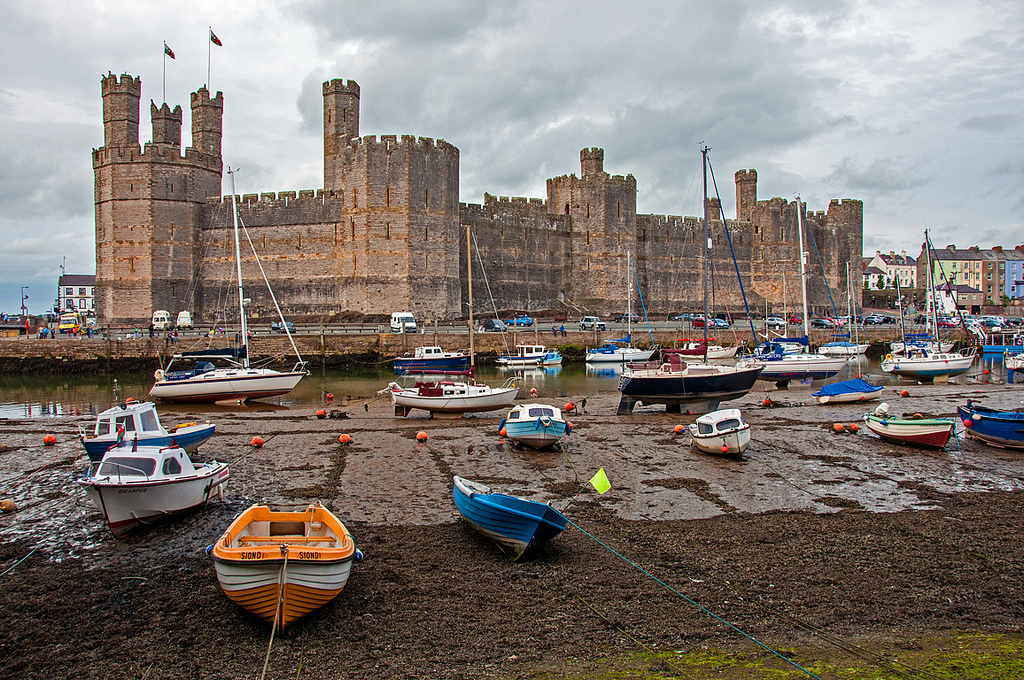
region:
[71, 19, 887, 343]
the castle is color brown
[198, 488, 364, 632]
the boat is white and orange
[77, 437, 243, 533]
the boat is white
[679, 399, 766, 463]
the boat is white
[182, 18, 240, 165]
a flag on a tower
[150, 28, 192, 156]
a flag on a tower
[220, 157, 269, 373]
a pole is color white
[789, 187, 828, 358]
a pole on a ship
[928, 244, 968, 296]
the building is green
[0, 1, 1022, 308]
A blue and white cloudy sky.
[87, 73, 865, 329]
A large brown castle.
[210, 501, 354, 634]
An orange and white boat.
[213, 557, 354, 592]
White strip on an orange boat.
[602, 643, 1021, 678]
Green moss ground in front of boats.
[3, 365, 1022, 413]
A green strip of water.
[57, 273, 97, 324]
White building behind the tallest part of the castle.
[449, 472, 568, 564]
A blue and silver boat tilted to the right next to an orange boat.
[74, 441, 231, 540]
A large white boat beside an orange one.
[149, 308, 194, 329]
Two white vans parked beside each other.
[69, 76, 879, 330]
the castle is brown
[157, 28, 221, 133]
two flags waving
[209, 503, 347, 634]
the boat is orange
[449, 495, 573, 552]
the boat is blue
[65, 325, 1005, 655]
the boats are on land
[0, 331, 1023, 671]
the river is dry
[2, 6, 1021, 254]
the sky is cloudy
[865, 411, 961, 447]
the boat has green stripe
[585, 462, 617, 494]
the flag is green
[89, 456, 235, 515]
the boat is white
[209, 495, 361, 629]
boat is orange and white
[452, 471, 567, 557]
boat is blue and white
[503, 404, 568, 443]
boat is small and blue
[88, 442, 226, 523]
boat is white and brown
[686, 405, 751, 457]
boat is small and white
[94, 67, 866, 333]
castle is large and made of stone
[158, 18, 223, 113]
two small flags on top of the castle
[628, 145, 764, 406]
small blue sailboat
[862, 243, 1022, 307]
multi story buildings are near the castle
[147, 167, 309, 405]
white sailboat is near the waterway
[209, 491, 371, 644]
an orange and white boat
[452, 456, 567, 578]
a blue boat on the ground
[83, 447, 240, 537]
a white boat on the ground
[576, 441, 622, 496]
a yellow flag on a line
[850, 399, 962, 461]
a small white boat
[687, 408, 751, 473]
a small white boat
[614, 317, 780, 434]
a white and black boat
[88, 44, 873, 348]
a large wooden castle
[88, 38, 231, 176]
three towers are on a castle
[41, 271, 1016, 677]
boats on the ground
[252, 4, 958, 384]
clouds in the sky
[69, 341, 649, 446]
water in the background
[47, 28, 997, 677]
castle in the background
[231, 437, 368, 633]
whie and orange boat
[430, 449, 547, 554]
blue boat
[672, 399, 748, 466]
white boat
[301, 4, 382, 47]
white clouds in blue sky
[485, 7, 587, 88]
white clouds in blue sky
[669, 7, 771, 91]
white clouds in blue sky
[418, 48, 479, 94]
white clouds in blue sky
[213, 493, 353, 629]
orange and white boat